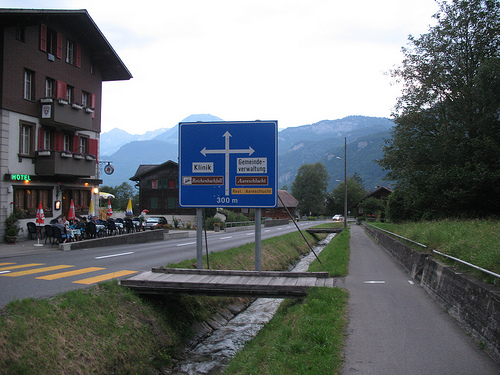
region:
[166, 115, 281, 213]
a blue road sign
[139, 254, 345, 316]
a small bridge to walk over the canal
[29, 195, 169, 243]
table and chairs sit outside the restaurant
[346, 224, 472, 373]
a walking trail or bike path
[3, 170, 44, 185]
the sign reads MOTEL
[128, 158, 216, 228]
a building is next to the Motel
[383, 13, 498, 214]
a big tree is on the other side of the trail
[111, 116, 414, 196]
a mountian can be seen in the distance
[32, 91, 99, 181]
the balconies for the upstairs rooms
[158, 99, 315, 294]
this is a street sign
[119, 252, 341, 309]
a small wooden bridge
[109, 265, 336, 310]
the bridge crosses over the ditch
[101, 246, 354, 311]
the wooden bridge crosses over the creek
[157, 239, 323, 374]
a small creek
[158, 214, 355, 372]
a small creek in a ditch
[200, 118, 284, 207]
there are white arrow on the sign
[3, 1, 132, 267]
this is a hotel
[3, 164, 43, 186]
a green neon sign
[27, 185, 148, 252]
the umbrellas are folded down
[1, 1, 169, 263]
a hotel with a green light on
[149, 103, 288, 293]
a roadway sign near mountains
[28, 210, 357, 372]
a walking bridge over a gulley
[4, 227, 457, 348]
a pedestrian crossing and walking bridge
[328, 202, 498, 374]
a footpath next to a wall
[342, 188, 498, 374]
a sidewalk next to a wall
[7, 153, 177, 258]
a hotel with an outdoor patio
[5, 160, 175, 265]
a hotel with a beer garden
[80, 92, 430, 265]
distant mountains in the Bavarian alps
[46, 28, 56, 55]
glass window on building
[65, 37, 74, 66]
glass window on building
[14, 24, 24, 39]
glass window on building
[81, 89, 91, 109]
glass window on building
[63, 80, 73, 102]
glass window on building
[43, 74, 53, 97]
glass window on building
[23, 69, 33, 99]
glass window on building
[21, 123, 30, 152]
glass window on building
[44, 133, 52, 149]
glass window on building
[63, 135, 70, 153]
glass window on building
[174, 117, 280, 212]
A blue street direction sign.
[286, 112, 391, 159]
A mountain in the background.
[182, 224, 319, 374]
A water stream running along side the road.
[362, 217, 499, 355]
A concrete wall holding back the grass.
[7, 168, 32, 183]
A green restaurant sign that is turned on.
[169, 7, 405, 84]
A cloudless sky.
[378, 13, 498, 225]
A tall tree on the right side.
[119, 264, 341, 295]
A bridge over running waters.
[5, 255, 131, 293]
Yellow markings in the middle of the road.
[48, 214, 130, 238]
People eating outside of a restaurant.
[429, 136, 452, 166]
green leaves on the tree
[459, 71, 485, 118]
green leaves on the tree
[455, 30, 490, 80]
green leaves on the tree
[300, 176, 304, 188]
green leaves on the tree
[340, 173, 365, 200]
green leaves on the tree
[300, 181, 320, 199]
green leaves on the tree